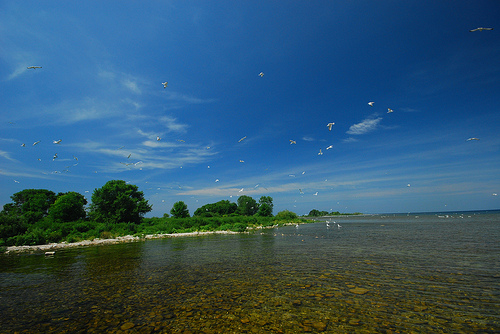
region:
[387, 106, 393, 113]
bird in the sky over shallow water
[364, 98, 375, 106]
bird in the sky over shallow water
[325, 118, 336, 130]
bird in the sky over shallow water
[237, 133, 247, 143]
bird in the sky over shallow water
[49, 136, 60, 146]
bird in the sky over shallow water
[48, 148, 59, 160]
bird in the sky over shallow water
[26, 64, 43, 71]
bird in the sky over shallow water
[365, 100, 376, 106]
white bird flying over the shallow water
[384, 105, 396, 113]
white bird flying over the shallow water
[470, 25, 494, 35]
white bird flying over the shallow water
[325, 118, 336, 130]
white bird flying over the shallow water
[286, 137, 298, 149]
white bird flying over the shallow water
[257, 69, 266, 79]
white bird flying over the shallow water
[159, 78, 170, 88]
white bird flying over the shallow water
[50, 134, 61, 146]
white bird flying over the shallow water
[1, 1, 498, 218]
a cloudy blue sky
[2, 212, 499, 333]
a shallow body of water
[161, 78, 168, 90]
a white bird in flight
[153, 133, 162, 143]
a white bird in flight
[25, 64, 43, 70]
a white bird in flight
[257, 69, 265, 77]
a white bird in flight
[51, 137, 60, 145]
a white bird in flight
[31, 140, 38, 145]
a white bird in flight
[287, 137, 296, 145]
a white bird in flight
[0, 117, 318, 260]
lush greenery on the side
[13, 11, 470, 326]
a bright and clear day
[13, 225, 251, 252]
rocks next to water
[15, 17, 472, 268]
birds flying in sky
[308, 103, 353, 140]
this is a bird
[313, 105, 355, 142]
the bird is white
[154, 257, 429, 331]
rocks on bottom of water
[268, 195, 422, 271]
birds on the water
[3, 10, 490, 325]
a bright and clear day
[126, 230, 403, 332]
the water is clear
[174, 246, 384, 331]
rocks on the bottom of water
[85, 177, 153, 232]
a tree that is very dark green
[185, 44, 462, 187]
a sky that is very dark blue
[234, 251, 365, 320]
some rocks that are in the water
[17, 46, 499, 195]
white birds flying in the sky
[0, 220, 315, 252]
A rocky edge to the water.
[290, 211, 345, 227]
white birds floating on the water.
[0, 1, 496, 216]
a blue sky with whispy white clouds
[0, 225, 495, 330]
Rocks underneath of the water.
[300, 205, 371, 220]
a piece of land in the distant background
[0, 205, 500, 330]
a body of water with a rocky bottom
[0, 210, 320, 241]
smaller bushes between the trees and the water.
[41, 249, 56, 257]
a small log floating on the water by the edge.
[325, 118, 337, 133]
A bird in the air.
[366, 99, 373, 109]
A bird in the air.